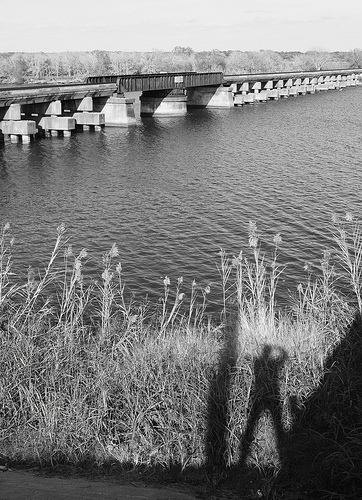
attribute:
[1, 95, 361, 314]
water — small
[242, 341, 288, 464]
shadow — photographer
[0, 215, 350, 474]
grass — high, tall, small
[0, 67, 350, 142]
bridge — long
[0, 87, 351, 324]
water — wind swept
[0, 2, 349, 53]
sky — white, clouded, cloudy, hazy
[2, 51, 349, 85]
area — wooded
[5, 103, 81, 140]
supports — large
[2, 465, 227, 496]
walkway — dirty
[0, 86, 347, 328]
body — water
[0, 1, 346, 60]
sky — empty, white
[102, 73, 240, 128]
bridge supports — large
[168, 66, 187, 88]
sign — white